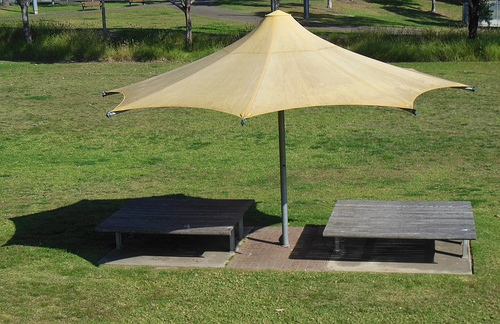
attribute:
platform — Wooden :
[322, 197, 476, 256]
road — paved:
[184, 1, 326, 42]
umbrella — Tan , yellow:
[98, 15, 460, 125]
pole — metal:
[258, 103, 300, 274]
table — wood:
[309, 169, 499, 272]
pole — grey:
[256, 109, 320, 258]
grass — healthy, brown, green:
[3, 63, 497, 323]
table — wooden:
[90, 188, 253, 258]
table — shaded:
[97, 197, 251, 257]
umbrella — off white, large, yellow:
[105, 10, 472, 242]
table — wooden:
[317, 197, 475, 269]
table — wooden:
[94, 194, 255, 252]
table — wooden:
[317, 201, 473, 262]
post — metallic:
[274, 108, 292, 249]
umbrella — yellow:
[103, 12, 473, 113]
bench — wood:
[79, 0, 109, 11]